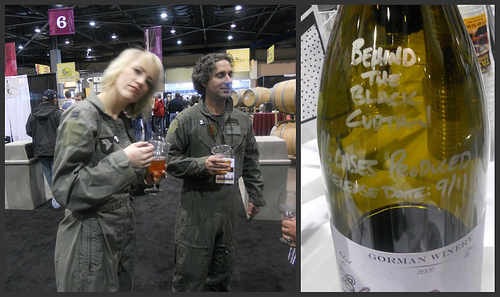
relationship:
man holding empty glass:
[191, 58, 259, 253] [201, 137, 239, 188]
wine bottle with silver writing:
[311, 14, 479, 294] [341, 33, 487, 223]